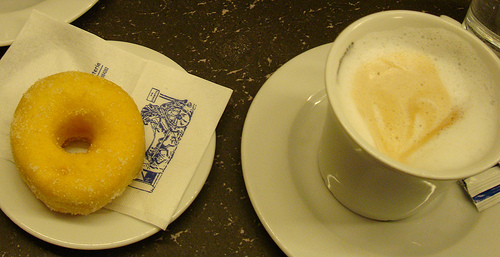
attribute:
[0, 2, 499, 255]
table — black, marble, dark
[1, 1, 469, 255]
spots — white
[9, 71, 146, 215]
donut — yellow, delicious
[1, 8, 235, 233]
napkin — white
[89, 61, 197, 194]
drawing — blue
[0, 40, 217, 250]
plate — round, white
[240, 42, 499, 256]
plate — round, white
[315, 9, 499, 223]
mug — white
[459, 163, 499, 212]
bag — blue, white